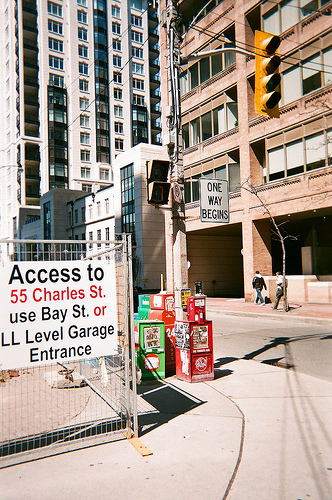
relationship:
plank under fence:
[124, 430, 152, 455] [0, 236, 138, 443]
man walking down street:
[273, 272, 289, 313] [205, 298, 330, 379]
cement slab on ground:
[6, 393, 227, 497] [6, 304, 329, 497]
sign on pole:
[200, 178, 229, 222] [166, 17, 186, 338]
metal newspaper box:
[190, 328, 206, 406] [185, 309, 219, 407]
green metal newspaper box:
[132, 316, 165, 383] [143, 330, 168, 407]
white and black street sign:
[193, 156, 241, 235] [201, 179, 225, 220]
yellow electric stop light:
[251, 77, 293, 95] [251, 28, 281, 120]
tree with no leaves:
[244, 166, 299, 317] [256, 189, 268, 266]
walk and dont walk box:
[142, 164, 178, 253] [142, 178, 168, 226]